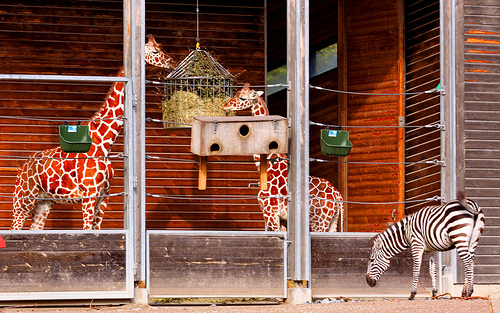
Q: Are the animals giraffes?
A: No, there are both giraffes and zebras.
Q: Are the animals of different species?
A: Yes, they are giraffes and zebras.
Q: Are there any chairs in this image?
A: No, there are no chairs.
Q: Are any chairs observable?
A: No, there are no chairs.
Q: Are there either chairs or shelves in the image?
A: No, there are no chairs or shelves.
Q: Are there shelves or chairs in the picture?
A: No, there are no chairs or shelves.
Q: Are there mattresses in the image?
A: No, there are no mattresses.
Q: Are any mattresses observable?
A: No, there are no mattresses.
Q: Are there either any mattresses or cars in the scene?
A: No, there are no mattresses or cars.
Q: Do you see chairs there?
A: No, there are no chairs.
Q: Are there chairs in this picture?
A: No, there are no chairs.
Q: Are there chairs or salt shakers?
A: No, there are no chairs or salt shakers.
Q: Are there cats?
A: No, there are no cats.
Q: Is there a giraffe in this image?
A: Yes, there are giraffes.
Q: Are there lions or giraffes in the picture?
A: Yes, there are giraffes.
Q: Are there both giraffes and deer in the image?
A: No, there are giraffes but no deer.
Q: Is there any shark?
A: No, there are no sharks.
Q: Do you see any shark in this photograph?
A: No, there are no sharks.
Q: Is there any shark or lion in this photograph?
A: No, there are no sharks or lions.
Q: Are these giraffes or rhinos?
A: These are giraffes.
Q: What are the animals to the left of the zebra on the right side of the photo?
A: The animals are giraffes.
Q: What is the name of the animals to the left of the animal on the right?
A: The animals are giraffes.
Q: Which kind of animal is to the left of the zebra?
A: The animals are giraffes.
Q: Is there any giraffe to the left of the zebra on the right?
A: Yes, there are giraffes to the left of the zebra.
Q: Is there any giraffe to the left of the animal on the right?
A: Yes, there are giraffes to the left of the zebra.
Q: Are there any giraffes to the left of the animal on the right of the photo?
A: Yes, there are giraffes to the left of the zebra.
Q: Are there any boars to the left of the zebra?
A: No, there are giraffes to the left of the zebra.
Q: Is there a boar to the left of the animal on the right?
A: No, there are giraffes to the left of the zebra.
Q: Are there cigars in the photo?
A: No, there are no cigars.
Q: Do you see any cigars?
A: No, there are no cigars.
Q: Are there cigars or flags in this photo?
A: No, there are no cigars or flags.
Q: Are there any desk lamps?
A: No, there are no desk lamps.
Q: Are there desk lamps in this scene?
A: No, there are no desk lamps.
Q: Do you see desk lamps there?
A: No, there are no desk lamps.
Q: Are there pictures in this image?
A: No, there are no pictures.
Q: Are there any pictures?
A: No, there are no pictures.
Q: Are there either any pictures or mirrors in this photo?
A: No, there are no pictures or mirrors.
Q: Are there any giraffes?
A: Yes, there is a giraffe.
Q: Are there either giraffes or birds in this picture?
A: Yes, there is a giraffe.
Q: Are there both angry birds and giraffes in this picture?
A: No, there is a giraffe but no angry birds.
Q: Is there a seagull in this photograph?
A: No, there are no seagulls.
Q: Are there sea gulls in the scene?
A: No, there are no sea gulls.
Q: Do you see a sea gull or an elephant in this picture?
A: No, there are no seagulls or elephants.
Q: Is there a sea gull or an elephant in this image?
A: No, there are no seagulls or elephants.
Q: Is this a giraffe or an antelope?
A: This is a giraffe.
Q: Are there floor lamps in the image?
A: No, there are no floor lamps.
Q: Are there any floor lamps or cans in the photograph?
A: No, there are no floor lamps or cans.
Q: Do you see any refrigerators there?
A: No, there are no refrigerators.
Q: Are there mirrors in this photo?
A: No, there are no mirrors.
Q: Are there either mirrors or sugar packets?
A: No, there are no mirrors or sugar packets.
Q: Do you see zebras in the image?
A: Yes, there is a zebra.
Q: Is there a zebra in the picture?
A: Yes, there is a zebra.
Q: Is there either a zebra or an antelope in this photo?
A: Yes, there is a zebra.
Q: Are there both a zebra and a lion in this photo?
A: No, there is a zebra but no lions.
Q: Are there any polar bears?
A: No, there are no polar bears.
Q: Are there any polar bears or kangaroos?
A: No, there are no polar bears or kangaroos.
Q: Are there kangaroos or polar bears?
A: No, there are no polar bears or kangaroos.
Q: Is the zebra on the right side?
A: Yes, the zebra is on the right of the image.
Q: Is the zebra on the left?
A: No, the zebra is on the right of the image.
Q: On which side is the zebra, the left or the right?
A: The zebra is on the right of the image.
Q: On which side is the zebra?
A: The zebra is on the right of the image.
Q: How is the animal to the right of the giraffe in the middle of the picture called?
A: The animal is a zebra.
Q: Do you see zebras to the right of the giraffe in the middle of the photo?
A: Yes, there is a zebra to the right of the giraffe.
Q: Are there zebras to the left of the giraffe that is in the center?
A: No, the zebra is to the right of the giraffe.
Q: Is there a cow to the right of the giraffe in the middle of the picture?
A: No, there is a zebra to the right of the giraffe.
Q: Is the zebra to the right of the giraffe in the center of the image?
A: Yes, the zebra is to the right of the giraffe.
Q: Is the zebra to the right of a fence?
A: No, the zebra is to the right of the giraffe.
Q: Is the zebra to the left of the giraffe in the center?
A: No, the zebra is to the right of the giraffe.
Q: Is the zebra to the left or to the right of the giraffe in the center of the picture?
A: The zebra is to the right of the giraffe.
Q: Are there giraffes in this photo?
A: Yes, there is a giraffe.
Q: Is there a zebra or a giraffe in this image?
A: Yes, there is a giraffe.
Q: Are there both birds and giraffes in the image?
A: No, there is a giraffe but no birds.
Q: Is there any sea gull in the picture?
A: No, there are no seagulls.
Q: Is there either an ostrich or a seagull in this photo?
A: No, there are no seagulls or ostriches.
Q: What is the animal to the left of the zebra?
A: The animal is a giraffe.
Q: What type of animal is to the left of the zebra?
A: The animal is a giraffe.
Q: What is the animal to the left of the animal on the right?
A: The animal is a giraffe.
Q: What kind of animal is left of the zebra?
A: The animal is a giraffe.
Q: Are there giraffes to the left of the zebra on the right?
A: Yes, there is a giraffe to the left of the zebra.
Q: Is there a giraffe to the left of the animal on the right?
A: Yes, there is a giraffe to the left of the zebra.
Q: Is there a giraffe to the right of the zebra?
A: No, the giraffe is to the left of the zebra.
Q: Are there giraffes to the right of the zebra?
A: No, the giraffe is to the left of the zebra.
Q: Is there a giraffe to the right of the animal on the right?
A: No, the giraffe is to the left of the zebra.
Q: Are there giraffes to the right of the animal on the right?
A: No, the giraffe is to the left of the zebra.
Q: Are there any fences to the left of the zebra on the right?
A: No, there is a giraffe to the left of the zebra.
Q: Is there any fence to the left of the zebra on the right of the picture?
A: No, there is a giraffe to the left of the zebra.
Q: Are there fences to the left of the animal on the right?
A: No, there is a giraffe to the left of the zebra.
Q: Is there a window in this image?
A: Yes, there are windows.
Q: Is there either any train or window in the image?
A: Yes, there are windows.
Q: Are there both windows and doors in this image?
A: No, there are windows but no doors.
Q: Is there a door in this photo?
A: No, there are no doors.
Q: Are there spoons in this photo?
A: No, there are no spoons.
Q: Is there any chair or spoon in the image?
A: No, there are no spoons or chairs.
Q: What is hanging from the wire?
A: The container is hanging from the wire.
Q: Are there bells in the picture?
A: No, there are no bells.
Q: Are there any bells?
A: No, there are no bells.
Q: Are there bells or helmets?
A: No, there are no bells or helmets.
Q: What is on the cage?
A: The cable is on the cage.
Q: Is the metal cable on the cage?
A: Yes, the cable is on the cage.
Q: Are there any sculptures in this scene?
A: No, there are no sculptures.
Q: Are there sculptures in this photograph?
A: No, there are no sculptures.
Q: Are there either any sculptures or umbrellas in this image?
A: No, there are no sculptures or umbrellas.